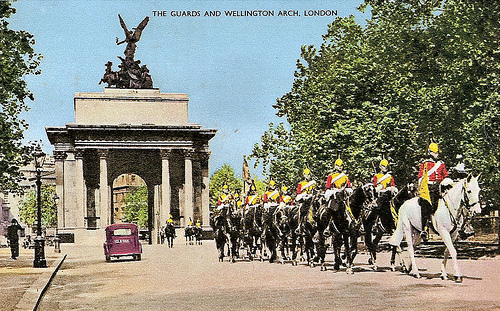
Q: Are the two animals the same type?
A: Yes, all the animals are horses.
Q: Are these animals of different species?
A: No, all the animals are horses.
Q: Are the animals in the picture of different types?
A: No, all the animals are horses.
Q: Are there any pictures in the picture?
A: No, there are no pictures.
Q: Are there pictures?
A: No, there are no pictures.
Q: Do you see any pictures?
A: No, there are no pictures.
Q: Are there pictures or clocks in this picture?
A: No, there are no pictures or clocks.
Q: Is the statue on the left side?
A: Yes, the statue is on the left of the image.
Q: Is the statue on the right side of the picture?
A: No, the statue is on the left of the image.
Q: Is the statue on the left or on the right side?
A: The statue is on the left of the image.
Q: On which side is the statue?
A: The statue is on the left of the image.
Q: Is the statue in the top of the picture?
A: Yes, the statue is in the top of the image.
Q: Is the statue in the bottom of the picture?
A: No, the statue is in the top of the image.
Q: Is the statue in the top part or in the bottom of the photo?
A: The statue is in the top of the image.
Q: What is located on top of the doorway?
A: The statue is on top of the doorway.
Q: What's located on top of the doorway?
A: The statue is on top of the doorway.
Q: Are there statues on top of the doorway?
A: Yes, there is a statue on top of the doorway.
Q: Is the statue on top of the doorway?
A: Yes, the statue is on top of the doorway.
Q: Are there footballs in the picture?
A: No, there are no footballs.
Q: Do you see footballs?
A: No, there are no footballs.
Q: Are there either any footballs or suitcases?
A: No, there are no footballs or suitcases.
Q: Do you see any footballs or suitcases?
A: No, there are no footballs or suitcases.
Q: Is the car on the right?
A: No, the car is on the left of the image.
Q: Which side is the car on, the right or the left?
A: The car is on the left of the image.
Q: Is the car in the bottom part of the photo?
A: Yes, the car is in the bottom of the image.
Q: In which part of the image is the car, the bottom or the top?
A: The car is in the bottom of the image.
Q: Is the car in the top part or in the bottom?
A: The car is in the bottom of the image.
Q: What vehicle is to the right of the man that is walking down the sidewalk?
A: The vehicle is a car.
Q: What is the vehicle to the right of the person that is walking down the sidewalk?
A: The vehicle is a car.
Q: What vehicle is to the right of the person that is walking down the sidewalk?
A: The vehicle is a car.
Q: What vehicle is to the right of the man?
A: The vehicle is a car.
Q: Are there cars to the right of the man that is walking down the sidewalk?
A: Yes, there is a car to the right of the man.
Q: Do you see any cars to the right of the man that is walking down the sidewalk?
A: Yes, there is a car to the right of the man.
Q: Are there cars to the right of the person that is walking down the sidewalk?
A: Yes, there is a car to the right of the man.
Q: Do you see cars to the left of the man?
A: No, the car is to the right of the man.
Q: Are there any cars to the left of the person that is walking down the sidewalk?
A: No, the car is to the right of the man.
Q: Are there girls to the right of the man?
A: No, there is a car to the right of the man.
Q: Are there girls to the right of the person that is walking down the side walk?
A: No, there is a car to the right of the man.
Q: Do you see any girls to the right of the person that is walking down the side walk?
A: No, there is a car to the right of the man.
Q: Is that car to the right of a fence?
A: No, the car is to the right of a man.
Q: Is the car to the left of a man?
A: No, the car is to the right of a man.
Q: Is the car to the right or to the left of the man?
A: The car is to the right of the man.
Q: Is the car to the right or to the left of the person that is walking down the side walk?
A: The car is to the right of the man.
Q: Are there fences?
A: No, there are no fences.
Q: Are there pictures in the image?
A: No, there are no pictures.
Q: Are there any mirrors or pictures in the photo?
A: No, there are no pictures or mirrors.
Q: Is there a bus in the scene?
A: No, there are no buses.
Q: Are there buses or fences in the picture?
A: No, there are no buses or fences.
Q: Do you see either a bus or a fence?
A: No, there are no buses or fences.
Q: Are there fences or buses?
A: No, there are no buses or fences.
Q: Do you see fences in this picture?
A: No, there are no fences.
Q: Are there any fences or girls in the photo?
A: No, there are no fences or girls.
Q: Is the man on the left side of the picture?
A: Yes, the man is on the left of the image.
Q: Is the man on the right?
A: No, the man is on the left of the image.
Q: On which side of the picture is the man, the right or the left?
A: The man is on the left of the image.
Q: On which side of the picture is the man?
A: The man is on the left of the image.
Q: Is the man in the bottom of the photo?
A: Yes, the man is in the bottom of the image.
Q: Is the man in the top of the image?
A: No, the man is in the bottom of the image.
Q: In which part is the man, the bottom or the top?
A: The man is in the bottom of the image.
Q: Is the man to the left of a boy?
A: No, the man is to the left of the car.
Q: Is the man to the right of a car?
A: No, the man is to the left of a car.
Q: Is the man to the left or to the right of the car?
A: The man is to the left of the car.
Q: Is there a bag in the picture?
A: No, there are no bags.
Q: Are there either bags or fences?
A: No, there are no bags or fences.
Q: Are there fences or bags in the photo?
A: No, there are no bags or fences.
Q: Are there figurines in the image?
A: No, there are no figurines.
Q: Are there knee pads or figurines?
A: No, there are no figurines or knee pads.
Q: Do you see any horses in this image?
A: Yes, there is a horse.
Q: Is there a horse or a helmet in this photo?
A: Yes, there is a horse.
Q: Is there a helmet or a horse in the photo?
A: Yes, there is a horse.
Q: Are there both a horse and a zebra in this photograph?
A: No, there is a horse but no zebras.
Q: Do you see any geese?
A: No, there are no geese.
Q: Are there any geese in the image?
A: No, there are no geese.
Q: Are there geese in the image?
A: No, there are no geese.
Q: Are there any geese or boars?
A: No, there are no geese or boars.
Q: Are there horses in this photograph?
A: Yes, there is a horse.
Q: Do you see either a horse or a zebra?
A: Yes, there is a horse.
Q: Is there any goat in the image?
A: No, there are no goats.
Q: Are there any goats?
A: No, there are no goats.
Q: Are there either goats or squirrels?
A: No, there are no goats or squirrels.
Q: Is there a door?
A: Yes, there is a door.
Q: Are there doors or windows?
A: Yes, there is a door.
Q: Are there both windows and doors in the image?
A: No, there is a door but no windows.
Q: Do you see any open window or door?
A: Yes, there is an open door.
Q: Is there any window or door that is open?
A: Yes, the door is open.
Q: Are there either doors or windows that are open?
A: Yes, the door is open.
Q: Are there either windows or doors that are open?
A: Yes, the door is open.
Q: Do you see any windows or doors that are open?
A: Yes, the door is open.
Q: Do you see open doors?
A: Yes, there is an open door.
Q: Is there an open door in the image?
A: Yes, there is an open door.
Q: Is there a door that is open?
A: Yes, there is a door that is open.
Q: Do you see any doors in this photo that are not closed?
A: Yes, there is a open door.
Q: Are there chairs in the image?
A: No, there are no chairs.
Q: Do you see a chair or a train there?
A: No, there are no chairs or trains.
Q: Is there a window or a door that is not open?
A: No, there is a door but it is open.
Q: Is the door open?
A: Yes, the door is open.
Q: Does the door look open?
A: Yes, the door is open.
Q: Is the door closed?
A: No, the door is open.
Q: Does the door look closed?
A: No, the door is open.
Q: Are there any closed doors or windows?
A: No, there is a door but it is open.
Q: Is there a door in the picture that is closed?
A: No, there is a door but it is open.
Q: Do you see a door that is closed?
A: No, there is a door but it is open.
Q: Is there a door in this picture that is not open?
A: No, there is a door but it is open.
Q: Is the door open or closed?
A: The door is open.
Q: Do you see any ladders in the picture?
A: No, there are no ladders.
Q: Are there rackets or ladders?
A: No, there are no ladders or rackets.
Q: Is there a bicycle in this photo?
A: No, there are no bicycles.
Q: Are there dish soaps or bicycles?
A: No, there are no bicycles or dish soaps.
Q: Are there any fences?
A: No, there are no fences.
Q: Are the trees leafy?
A: Yes, the trees are leafy.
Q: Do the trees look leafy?
A: Yes, the trees are leafy.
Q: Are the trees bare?
A: No, the trees are leafy.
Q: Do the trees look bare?
A: No, the trees are leafy.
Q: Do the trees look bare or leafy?
A: The trees are leafy.